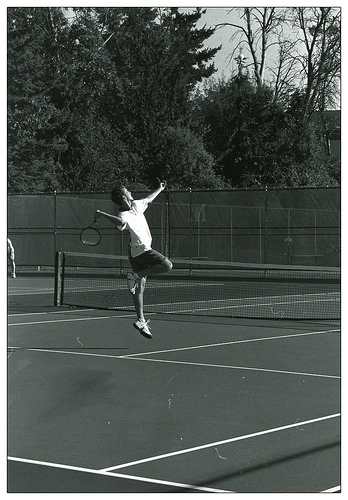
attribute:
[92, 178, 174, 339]
person — playing tennis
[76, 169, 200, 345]
man — jumping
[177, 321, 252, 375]
tennis court — large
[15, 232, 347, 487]
court — tennis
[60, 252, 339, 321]
netting — tennis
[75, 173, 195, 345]
player — tennis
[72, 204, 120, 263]
racquet — mid swing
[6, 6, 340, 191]
trees — multiple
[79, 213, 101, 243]
racquet — tennis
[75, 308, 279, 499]
lines — white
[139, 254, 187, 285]
leg — bent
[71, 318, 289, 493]
lines — white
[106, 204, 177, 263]
shirt — white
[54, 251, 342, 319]
net — black